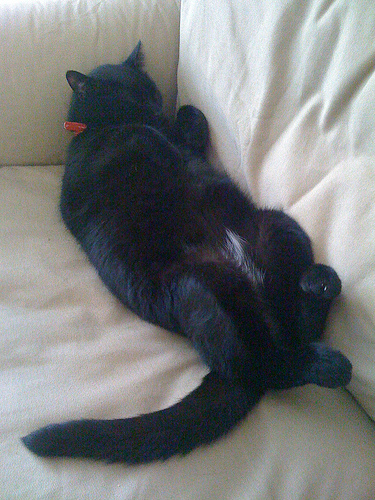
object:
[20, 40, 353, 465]
cat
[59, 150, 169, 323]
back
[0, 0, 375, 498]
sofa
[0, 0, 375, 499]
scene